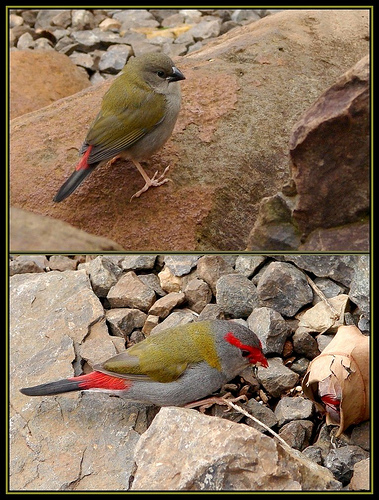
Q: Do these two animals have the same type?
A: Yes, all the animals are birds.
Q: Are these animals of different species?
A: No, all the animals are birds.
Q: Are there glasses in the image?
A: No, there are no glasses.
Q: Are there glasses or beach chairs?
A: No, there are no glasses or beach chairs.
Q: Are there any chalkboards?
A: No, there are no chalkboards.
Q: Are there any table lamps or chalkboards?
A: No, there are no chalkboards or table lamps.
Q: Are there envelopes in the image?
A: No, there are no envelopes.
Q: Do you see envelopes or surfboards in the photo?
A: No, there are no envelopes or surfboards.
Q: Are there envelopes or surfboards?
A: No, there are no envelopes or surfboards.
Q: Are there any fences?
A: No, there are no fences.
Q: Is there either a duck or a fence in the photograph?
A: No, there are no fences or ducks.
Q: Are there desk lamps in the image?
A: No, there are no desk lamps.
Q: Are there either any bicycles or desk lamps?
A: No, there are no desk lamps or bicycles.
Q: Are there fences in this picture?
A: No, there are no fences.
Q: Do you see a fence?
A: No, there are no fences.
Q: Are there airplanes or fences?
A: No, there are no fences or airplanes.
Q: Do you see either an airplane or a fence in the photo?
A: No, there are no fences or airplanes.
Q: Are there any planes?
A: No, there are no planes.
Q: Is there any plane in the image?
A: No, there are no airplanes.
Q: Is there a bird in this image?
A: Yes, there is a bird.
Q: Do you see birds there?
A: Yes, there is a bird.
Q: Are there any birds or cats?
A: Yes, there is a bird.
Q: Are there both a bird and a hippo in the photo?
A: No, there is a bird but no hippoes.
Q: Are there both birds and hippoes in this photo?
A: No, there is a bird but no hippoes.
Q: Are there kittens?
A: No, there are no kittens.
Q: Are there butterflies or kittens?
A: No, there are no kittens or butterflies.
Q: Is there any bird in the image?
A: Yes, there is a bird.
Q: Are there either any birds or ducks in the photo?
A: Yes, there is a bird.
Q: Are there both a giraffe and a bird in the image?
A: No, there is a bird but no giraffes.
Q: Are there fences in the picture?
A: No, there are no fences.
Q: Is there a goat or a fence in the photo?
A: No, there are no fences or goats.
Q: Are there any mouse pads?
A: No, there are no mouse pads.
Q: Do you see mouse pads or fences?
A: No, there are no mouse pads or fences.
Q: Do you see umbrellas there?
A: No, there are no umbrellas.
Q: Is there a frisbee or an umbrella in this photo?
A: No, there are no umbrellas or frisbees.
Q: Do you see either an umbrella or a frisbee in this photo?
A: No, there are no umbrellas or frisbees.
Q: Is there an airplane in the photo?
A: No, there are no airplanes.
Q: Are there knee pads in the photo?
A: No, there are no knee pads.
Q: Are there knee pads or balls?
A: No, there are no knee pads or balls.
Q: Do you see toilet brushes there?
A: No, there are no toilet brushes.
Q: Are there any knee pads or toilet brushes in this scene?
A: No, there are no toilet brushes or knee pads.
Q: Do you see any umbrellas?
A: No, there are no umbrellas.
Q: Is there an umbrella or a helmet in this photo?
A: No, there are no umbrellas or helmets.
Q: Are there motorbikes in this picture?
A: No, there are no motorbikes.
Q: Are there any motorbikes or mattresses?
A: No, there are no motorbikes or mattresses.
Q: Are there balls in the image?
A: No, there are no balls.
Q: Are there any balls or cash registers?
A: No, there are no balls or cash registers.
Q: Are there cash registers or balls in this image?
A: No, there are no balls or cash registers.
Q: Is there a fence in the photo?
A: No, there are no fences.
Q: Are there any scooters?
A: No, there are no scooters.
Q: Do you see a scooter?
A: No, there are no scooters.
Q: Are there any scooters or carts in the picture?
A: No, there are no scooters or carts.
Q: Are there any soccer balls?
A: No, there are no soccer balls.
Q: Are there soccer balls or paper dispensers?
A: No, there are no soccer balls or paper dispensers.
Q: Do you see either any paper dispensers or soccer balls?
A: No, there are no soccer balls or paper dispensers.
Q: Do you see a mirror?
A: No, there are no mirrors.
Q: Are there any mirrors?
A: No, there are no mirrors.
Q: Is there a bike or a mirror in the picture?
A: No, there are no mirrors or bikes.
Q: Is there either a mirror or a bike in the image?
A: No, there are no mirrors or bikes.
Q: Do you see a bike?
A: No, there are no bikes.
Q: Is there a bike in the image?
A: No, there are no bikes.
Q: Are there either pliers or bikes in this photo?
A: No, there are no bikes or pliers.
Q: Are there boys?
A: No, there are no boys.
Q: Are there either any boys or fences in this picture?
A: No, there are no boys or fences.